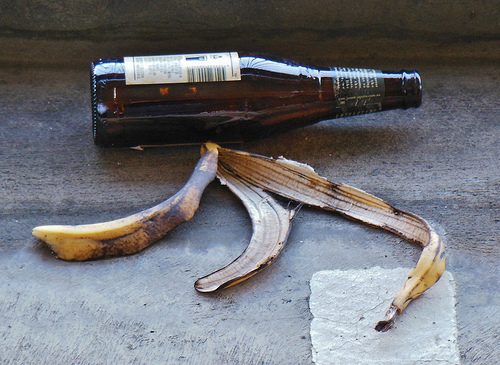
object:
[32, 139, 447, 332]
peel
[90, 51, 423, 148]
bottle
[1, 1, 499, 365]
floor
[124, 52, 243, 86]
label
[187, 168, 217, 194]
part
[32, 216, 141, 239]
part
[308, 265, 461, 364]
patch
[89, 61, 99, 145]
bottom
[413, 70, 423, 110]
lip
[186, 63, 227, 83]
upc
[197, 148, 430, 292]
inside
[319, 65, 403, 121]
neck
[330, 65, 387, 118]
label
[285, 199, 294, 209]
string